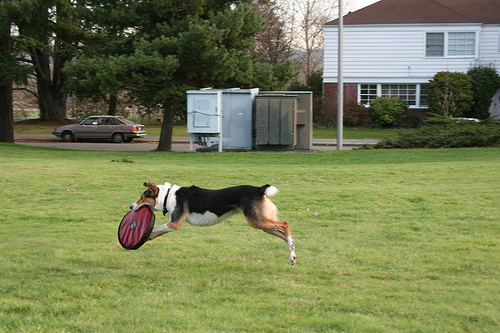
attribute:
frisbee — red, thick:
[124, 206, 157, 247]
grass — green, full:
[344, 148, 422, 262]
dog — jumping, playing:
[133, 169, 315, 265]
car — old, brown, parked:
[58, 114, 146, 139]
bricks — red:
[326, 77, 343, 128]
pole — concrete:
[337, 8, 349, 162]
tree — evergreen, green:
[138, 78, 179, 175]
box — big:
[180, 86, 260, 155]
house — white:
[333, 14, 500, 77]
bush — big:
[436, 66, 472, 142]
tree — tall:
[299, 2, 323, 117]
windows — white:
[358, 90, 381, 110]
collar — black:
[160, 192, 171, 211]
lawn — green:
[19, 150, 146, 330]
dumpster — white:
[183, 87, 267, 164]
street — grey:
[36, 135, 141, 152]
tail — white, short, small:
[255, 182, 276, 204]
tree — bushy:
[433, 81, 464, 113]